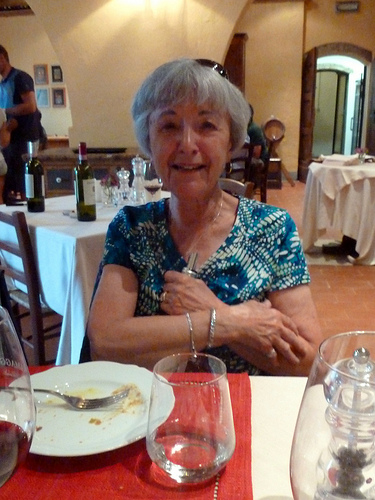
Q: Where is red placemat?
A: On table.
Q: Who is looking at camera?
A: A woman.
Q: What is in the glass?
A: Nothing.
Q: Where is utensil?
A: On plate.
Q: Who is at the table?
A: A woman.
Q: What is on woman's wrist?
A: Bracelet.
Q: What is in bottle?
A: Wine.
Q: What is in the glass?
A: Nothing.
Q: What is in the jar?
A: Pepper.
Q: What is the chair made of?
A: Wood.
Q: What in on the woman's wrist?
A: Bracelets.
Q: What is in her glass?
A: Nothing.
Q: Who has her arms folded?
A: The woman.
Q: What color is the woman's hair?
A: Gray.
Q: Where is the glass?
A: Table.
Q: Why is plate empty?
A: Food was eaten.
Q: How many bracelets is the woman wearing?
A: Two.